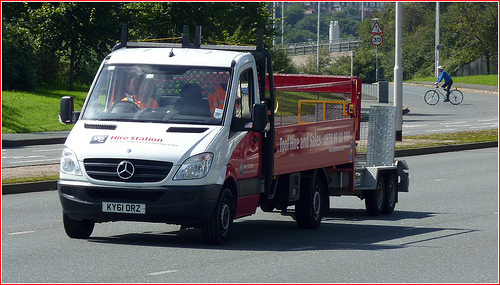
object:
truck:
[56, 42, 415, 241]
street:
[0, 82, 500, 284]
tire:
[204, 183, 238, 246]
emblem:
[115, 159, 137, 179]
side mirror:
[250, 98, 273, 135]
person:
[433, 66, 453, 100]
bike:
[422, 84, 466, 106]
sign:
[369, 20, 385, 89]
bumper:
[57, 182, 224, 225]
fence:
[278, 37, 364, 56]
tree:
[445, 1, 500, 76]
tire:
[63, 208, 96, 238]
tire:
[293, 178, 325, 224]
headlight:
[173, 151, 214, 180]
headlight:
[57, 147, 84, 176]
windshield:
[80, 64, 231, 125]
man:
[110, 76, 160, 114]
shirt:
[119, 96, 162, 111]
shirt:
[436, 72, 453, 85]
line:
[148, 267, 176, 278]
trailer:
[255, 71, 412, 227]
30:
[373, 36, 380, 45]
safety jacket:
[207, 85, 238, 120]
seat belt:
[121, 92, 138, 104]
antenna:
[167, 28, 176, 57]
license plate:
[103, 201, 150, 214]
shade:
[87, 206, 477, 252]